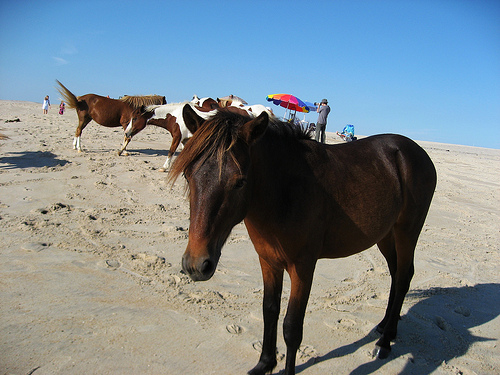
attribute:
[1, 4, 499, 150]
sky — blue, clear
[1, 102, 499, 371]
sand — brown, tan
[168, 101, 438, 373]
horse — brown, here, standing, white, black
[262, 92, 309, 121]
umbrella — multicolored, colorful, rainbow colored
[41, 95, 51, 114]
person — walking